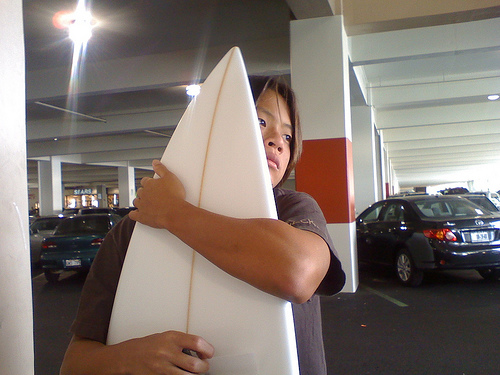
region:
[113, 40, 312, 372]
A person holding the surf board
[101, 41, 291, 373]
White color surboard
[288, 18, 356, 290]
Pillar of the building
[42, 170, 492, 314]
Lot of cars parked under the building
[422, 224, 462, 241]
Side indicator of the car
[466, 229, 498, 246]
Number plate of the car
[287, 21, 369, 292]
White and brown color pillar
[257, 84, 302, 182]
Face of the person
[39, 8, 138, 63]
Light is glowing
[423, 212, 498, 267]
Back side of the car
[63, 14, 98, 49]
a bright ceiling light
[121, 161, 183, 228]
the hand of a boy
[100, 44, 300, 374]
part of a white surfboard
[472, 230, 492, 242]
a license plate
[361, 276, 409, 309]
a white line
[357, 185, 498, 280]
part of a gray car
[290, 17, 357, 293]
a large red and white pole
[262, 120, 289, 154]
the nose of a boy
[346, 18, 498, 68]
a large white beam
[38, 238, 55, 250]
the taillight of a car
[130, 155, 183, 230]
The person's right hand.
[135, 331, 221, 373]
The person's left hand.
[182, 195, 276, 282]
The forearm of the person's right arm.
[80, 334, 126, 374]
The forearm of the person's left arm.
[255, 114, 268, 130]
The left eye of the person.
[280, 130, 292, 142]
The right eye of the person.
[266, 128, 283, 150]
The nose of the person.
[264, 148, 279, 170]
The mouth of the person.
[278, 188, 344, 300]
The right sleeve of the person's shirt.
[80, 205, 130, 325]
The left sleeve of the person's shirt.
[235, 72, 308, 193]
Person is of Asian, Pacific Islander descent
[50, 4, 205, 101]
Parking garage is well lit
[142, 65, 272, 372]
Person is holding a surf board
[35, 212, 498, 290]
Parking Garage is full of cars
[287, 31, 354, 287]
Parking Garage has structure painted white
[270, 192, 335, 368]
Person is wearing neutral shirt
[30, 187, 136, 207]
Stores are visible from within parking garage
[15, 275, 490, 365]
Garage is paved black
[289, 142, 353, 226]
Columns have red bands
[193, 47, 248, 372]
Surf board has a thin, yellow line straight down the middle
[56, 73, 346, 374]
a woman holding a surfboard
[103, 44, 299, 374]
a white surfboard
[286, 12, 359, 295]
a red and white pillar behind the woman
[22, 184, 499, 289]
cars parked in the garage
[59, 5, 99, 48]
a bright light in the garage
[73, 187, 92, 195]
Sears logo behind the woman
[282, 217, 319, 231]
writing on woman's shirt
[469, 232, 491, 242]
license plate on black car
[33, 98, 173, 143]
a pipe running through the ceiling beams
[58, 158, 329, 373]
muscular arms on the woman